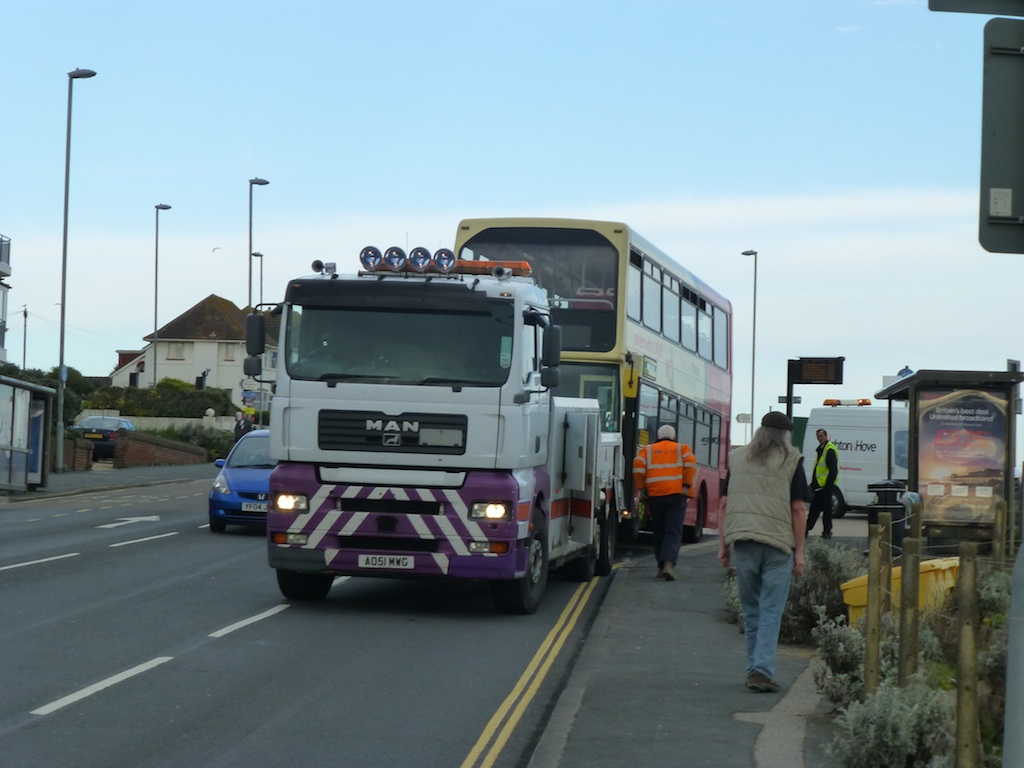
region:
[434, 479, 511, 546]
light on a truck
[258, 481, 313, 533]
light on a truck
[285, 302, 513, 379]
window on a truck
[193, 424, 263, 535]
car on a street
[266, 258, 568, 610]
truck on a street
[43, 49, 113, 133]
light on a pole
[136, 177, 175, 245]
light on a pole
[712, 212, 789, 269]
light on a pole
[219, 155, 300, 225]
light on a pole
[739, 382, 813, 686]
a person walking on a sidewalk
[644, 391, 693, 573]
a person walking on a sidewalk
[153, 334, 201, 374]
a window on a building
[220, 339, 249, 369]
a window on a building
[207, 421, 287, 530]
a car on a street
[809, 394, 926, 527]
a car on a street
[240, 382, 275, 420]
a window on a building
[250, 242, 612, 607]
white tractor of truck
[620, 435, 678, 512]
man has orange jacket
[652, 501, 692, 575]
man has blue pants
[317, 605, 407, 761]
road is dark grey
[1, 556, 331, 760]
white lines on road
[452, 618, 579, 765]
yellow lines on shoulder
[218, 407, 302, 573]
blue car behind truck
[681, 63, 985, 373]
blue and white sky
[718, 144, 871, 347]
white clouds are faint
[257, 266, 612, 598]
A truck cab on a road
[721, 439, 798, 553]
A beige vest on a man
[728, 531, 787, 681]
Blue jeans on a man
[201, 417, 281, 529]
A small blue car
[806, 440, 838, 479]
A yellow vest on a man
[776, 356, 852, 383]
A sign on a pole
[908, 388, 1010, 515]
A sign on a bus shelter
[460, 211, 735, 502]
A bus being towed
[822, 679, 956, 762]
A plant near a road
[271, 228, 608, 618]
large white and purple truck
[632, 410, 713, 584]
man wearing orange safety vest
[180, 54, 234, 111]
white clouds in blue sky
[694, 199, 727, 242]
white clouds in blue sky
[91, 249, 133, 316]
white clouds in blue sky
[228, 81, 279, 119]
white clouds in blue sky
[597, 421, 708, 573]
Man in orange jacket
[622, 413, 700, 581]
Man in blue pants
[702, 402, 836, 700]
Man wearing black cap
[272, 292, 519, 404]
A window on a vehicle.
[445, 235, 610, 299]
A window on a vehicle.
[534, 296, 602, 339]
A window on a vehicle.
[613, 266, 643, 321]
A window on a vehicle.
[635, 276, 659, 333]
A window on a vehicle.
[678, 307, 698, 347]
A window on a vehicle.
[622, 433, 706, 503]
orange colored safety vest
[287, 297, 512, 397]
windshield on a truck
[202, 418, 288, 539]
blue car on a road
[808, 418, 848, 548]
man with a yellow safety vest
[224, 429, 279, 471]
windshield on a blue car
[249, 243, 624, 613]
truck towing a bus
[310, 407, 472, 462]
grill on a bus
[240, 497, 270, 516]
license plate on a car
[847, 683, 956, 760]
A shrub in the ground.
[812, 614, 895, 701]
A shrub in the ground.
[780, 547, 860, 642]
A shrub in the ground.